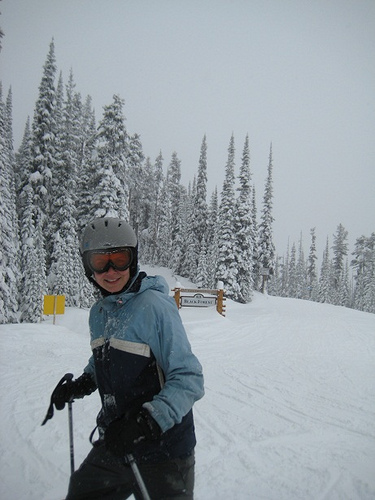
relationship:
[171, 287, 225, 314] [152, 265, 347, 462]
sign on ski slope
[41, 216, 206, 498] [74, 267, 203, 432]
female wearing jacket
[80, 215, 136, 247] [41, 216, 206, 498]
helmet on top of female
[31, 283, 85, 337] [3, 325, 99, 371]
sign above snow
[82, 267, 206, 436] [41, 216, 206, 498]
jacket on female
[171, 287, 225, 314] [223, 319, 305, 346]
sign on top of snow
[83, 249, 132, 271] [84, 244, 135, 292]
goggles on face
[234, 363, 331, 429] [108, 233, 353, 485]
tracks in snow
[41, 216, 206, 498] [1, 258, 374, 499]
female on top of snow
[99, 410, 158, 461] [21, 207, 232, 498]
hand of person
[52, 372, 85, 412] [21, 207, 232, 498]
hand of person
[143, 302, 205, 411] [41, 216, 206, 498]
arm of female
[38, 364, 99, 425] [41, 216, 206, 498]
hand of female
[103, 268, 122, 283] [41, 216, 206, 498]
nose of female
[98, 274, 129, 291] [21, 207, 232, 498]
smile of person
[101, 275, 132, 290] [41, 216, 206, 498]
mouth of female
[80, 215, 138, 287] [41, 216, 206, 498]
helmet of female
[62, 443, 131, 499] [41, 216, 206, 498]
leg of female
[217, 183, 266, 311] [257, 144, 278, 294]
snow on pine tree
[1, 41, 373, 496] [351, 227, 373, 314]
snow on tree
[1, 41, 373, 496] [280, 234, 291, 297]
snow on tree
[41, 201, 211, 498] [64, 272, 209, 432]
female with jacket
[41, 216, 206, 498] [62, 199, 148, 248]
female in helmet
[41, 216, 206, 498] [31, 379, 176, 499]
female with ski poles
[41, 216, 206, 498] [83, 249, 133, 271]
female in goggles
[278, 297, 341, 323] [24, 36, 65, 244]
slope with pine tree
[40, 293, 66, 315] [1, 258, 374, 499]
sign in snow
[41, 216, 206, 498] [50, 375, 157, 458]
female wearing gloves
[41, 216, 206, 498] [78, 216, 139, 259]
female wearing helmet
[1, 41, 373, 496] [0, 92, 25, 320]
snow covering pine tree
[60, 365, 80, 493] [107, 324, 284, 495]
ski pole in hand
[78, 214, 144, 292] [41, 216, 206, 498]
head of a female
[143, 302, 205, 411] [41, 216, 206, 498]
arm of a female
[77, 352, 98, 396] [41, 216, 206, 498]
arm of a female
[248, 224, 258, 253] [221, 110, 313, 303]
snow on tree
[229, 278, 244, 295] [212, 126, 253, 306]
snow on tree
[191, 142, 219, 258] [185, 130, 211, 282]
snow on pine tree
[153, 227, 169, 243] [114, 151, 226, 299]
snow on tree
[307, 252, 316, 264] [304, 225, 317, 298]
snow on pine tree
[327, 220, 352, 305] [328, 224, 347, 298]
snow on tree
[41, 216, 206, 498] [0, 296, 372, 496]
female on slope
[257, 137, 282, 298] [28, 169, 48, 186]
pine tree covered in snow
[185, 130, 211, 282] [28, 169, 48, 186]
pine tree covered in snow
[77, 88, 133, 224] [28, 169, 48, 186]
pine tree covered in snow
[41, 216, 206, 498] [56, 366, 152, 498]
female holding ski poles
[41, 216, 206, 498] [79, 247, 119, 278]
female wearing goggles